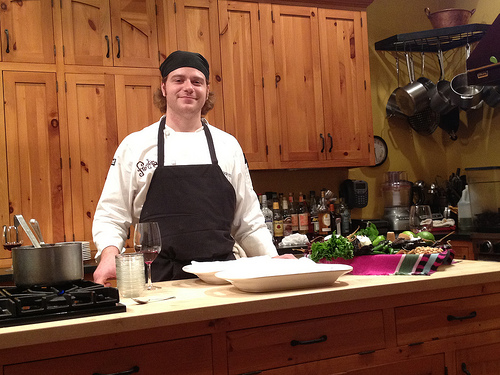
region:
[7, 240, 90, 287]
metal pot on the stove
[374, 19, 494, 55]
metal rack holding hanging pots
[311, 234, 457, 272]
tray of a variety of foods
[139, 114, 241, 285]
the man's black apron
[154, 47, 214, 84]
black banana on the man's head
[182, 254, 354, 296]
white trays in front of the man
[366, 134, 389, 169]
black and white clock on the wall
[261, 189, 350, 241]
bottles on the counter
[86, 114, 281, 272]
the man's white shirt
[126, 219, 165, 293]
glass of wine in front of the man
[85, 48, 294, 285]
A man with an apron on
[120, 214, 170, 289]
a glass of red wine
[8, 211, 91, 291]
a cooking ware with a scoop inside it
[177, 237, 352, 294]
two large plates on a table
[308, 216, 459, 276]
ingredients for a recipe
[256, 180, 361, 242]
Spices and a wide range of alcohols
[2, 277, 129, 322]
cooking stove made out of steel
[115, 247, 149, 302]
an opened can on a tabletop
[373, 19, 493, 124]
cooking ware hanged on top of a platform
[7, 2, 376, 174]
cabinets made out of wood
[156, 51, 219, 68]
The chef has a black cap.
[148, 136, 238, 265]
The man is wearing a black apron.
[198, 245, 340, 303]
Two white plate on the counter.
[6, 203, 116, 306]
A pot on the stovetop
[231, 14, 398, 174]
Cabinets in the picture.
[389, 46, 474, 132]
Pots hanging on the rack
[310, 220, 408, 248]
Food on the table.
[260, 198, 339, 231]
Bottle of liquor under the cabinet.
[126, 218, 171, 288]
A glass of wine on the table.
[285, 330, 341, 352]
Handles on the drawer.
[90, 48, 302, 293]
Chef with a black apron in the kitchen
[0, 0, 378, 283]
Wooden wall cabinets behind the chef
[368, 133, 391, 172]
Clock hanging on the back wall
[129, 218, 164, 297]
Glass of wine in front of the chef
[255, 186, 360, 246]
Group of liquor bottles to the right of the chef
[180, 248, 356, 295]
Two white empty platters in front of the chef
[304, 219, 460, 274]
Platter of produce next to the white platters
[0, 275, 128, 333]
Burners on top of the countertop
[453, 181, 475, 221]
White one gallon jug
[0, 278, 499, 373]
Wooden floor cabinets in front of the chef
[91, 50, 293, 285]
a male chef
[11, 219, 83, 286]
a metal pot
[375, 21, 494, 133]
a black hanging pot rack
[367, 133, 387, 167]
a black and white wall clock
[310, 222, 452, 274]
a tray of fresh vegetables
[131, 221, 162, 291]
a long stemmed glass of wine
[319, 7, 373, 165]
a brown wood cabinet door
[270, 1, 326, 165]
a brown wood cabinet door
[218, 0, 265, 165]
a brown wood cabinet door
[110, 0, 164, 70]
a brown wood cabinet door